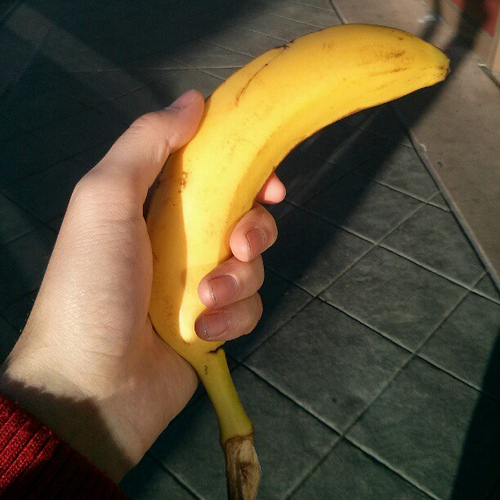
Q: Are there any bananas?
A: Yes, there is a banana.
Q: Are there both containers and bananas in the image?
A: No, there is a banana but no containers.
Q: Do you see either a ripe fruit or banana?
A: Yes, there is a ripe banana.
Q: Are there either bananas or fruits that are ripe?
A: Yes, the banana is ripe.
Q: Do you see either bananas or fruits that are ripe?
A: Yes, the banana is ripe.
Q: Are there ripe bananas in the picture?
A: Yes, there is a ripe banana.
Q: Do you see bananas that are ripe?
A: Yes, there is a banana that is ripe.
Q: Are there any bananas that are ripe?
A: Yes, there is a banana that is ripe.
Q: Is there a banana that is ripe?
A: Yes, there is a banana that is ripe.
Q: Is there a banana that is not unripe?
A: Yes, there is an ripe banana.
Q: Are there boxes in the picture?
A: No, there are no boxes.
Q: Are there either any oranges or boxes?
A: No, there are no boxes or oranges.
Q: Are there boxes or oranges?
A: No, there are no boxes or oranges.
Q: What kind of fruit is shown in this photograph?
A: The fruit is a banana.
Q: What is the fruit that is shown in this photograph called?
A: The fruit is a banana.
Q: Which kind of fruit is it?
A: The fruit is a banana.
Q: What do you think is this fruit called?
A: This is a banana.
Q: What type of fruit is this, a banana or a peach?
A: This is a banana.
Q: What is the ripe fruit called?
A: The fruit is a banana.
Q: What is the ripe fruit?
A: The fruit is a banana.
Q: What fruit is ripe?
A: The fruit is a banana.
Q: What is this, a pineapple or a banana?
A: This is a banana.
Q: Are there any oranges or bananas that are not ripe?
A: No, there is a banana but it is ripe.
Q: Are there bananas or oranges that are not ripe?
A: No, there is a banana but it is ripe.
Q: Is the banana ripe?
A: Yes, the banana is ripe.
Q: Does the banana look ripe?
A: Yes, the banana is ripe.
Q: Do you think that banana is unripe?
A: No, the banana is ripe.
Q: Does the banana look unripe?
A: No, the banana is ripe.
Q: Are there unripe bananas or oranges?
A: No, there is a banana but it is ripe.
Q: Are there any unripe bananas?
A: No, there is a banana but it is ripe.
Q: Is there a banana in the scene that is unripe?
A: No, there is a banana but it is ripe.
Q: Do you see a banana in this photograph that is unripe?
A: No, there is a banana but it is ripe.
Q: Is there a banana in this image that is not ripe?
A: No, there is a banana but it is ripe.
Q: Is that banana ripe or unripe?
A: The banana is ripe.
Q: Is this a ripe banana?
A: Yes, this is a ripe banana.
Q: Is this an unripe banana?
A: No, this is a ripe banana.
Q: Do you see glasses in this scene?
A: No, there are no glasses.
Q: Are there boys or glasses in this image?
A: No, there are no glasses or boys.